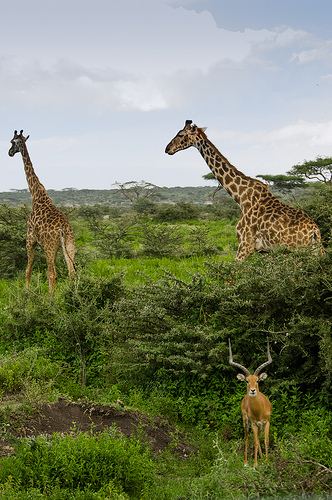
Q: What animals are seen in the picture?
A: Two giraffes and one deer.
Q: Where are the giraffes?
A: The giraffes are walking on grassy land.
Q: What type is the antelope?
A: This is an Impala deer.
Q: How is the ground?
A: Covered with shrubs, grass and small trees.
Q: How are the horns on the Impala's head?
A: Long and curved.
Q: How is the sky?
A: Grey and cloudy.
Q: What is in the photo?
A: Animals.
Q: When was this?
A: Daytime.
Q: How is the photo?
A: Clear.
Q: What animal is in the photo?
A: Giraffes.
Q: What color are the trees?
A: Green.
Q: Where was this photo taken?
A: In Africa.